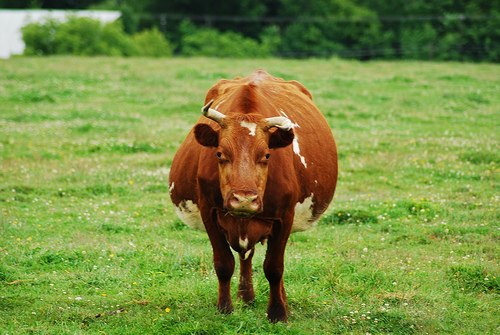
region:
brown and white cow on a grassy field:
[166, 68, 341, 323]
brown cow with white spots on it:
[166, 68, 341, 324]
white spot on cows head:
[238, 119, 259, 137]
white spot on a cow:
[290, 135, 311, 169]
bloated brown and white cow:
[165, 66, 342, 323]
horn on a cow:
[200, 95, 232, 124]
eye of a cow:
[212, 148, 229, 161]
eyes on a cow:
[214, 145, 271, 162]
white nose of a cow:
[224, 190, 262, 210]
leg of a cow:
[199, 202, 238, 315]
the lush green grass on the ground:
[0, 55, 497, 334]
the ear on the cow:
[194, 123, 218, 146]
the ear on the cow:
[269, 128, 294, 148]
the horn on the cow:
[200, 98, 225, 125]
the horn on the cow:
[265, 115, 292, 128]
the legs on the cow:
[197, 206, 294, 322]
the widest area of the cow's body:
[168, 68, 337, 234]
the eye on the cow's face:
[215, 150, 228, 160]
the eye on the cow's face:
[259, 152, 270, 161]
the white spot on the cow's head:
[239, 118, 256, 135]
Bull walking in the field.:
[151, 31, 346, 331]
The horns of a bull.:
[193, 98, 304, 137]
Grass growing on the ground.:
[26, 74, 135, 229]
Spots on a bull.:
[277, 109, 344, 261]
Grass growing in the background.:
[39, 12, 488, 65]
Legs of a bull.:
[187, 232, 329, 334]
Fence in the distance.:
[6, 6, 151, 56]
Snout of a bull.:
[223, 186, 268, 218]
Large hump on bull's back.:
[225, 75, 263, 115]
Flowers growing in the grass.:
[408, 128, 495, 192]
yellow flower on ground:
[19, 230, 38, 254]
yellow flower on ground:
[102, 247, 131, 271]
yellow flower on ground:
[154, 299, 180, 320]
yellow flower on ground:
[120, 267, 152, 296]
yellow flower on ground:
[398, 244, 417, 273]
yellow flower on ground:
[431, 224, 459, 255]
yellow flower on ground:
[418, 177, 444, 216]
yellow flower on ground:
[404, 147, 434, 194]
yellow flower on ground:
[406, 129, 424, 162]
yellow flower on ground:
[344, 139, 360, 163]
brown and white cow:
[157, 70, 365, 322]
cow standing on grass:
[148, 50, 390, 332]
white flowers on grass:
[53, 73, 106, 122]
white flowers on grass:
[40, 141, 100, 197]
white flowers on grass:
[15, 154, 55, 203]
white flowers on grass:
[15, 217, 44, 278]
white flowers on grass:
[77, 272, 129, 329]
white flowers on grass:
[391, 266, 413, 308]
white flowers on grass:
[331, 298, 377, 331]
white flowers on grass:
[352, 225, 381, 280]